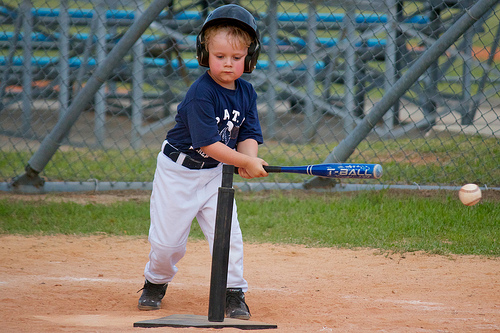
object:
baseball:
[459, 184, 481, 206]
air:
[0, 0, 498, 330]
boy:
[136, 3, 382, 320]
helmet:
[196, 3, 260, 73]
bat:
[235, 163, 384, 179]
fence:
[0, 0, 498, 195]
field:
[0, 138, 499, 333]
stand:
[132, 164, 278, 330]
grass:
[2, 137, 499, 257]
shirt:
[165, 70, 263, 163]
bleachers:
[1, 7, 431, 71]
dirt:
[0, 235, 498, 333]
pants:
[143, 139, 247, 292]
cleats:
[137, 275, 249, 320]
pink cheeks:
[208, 32, 248, 82]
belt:
[163, 143, 220, 169]